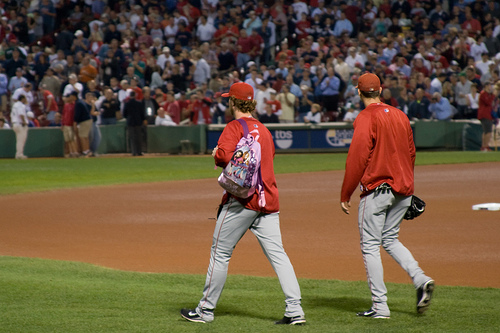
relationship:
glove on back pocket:
[375, 182, 391, 192] [375, 187, 395, 213]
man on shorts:
[69, 87, 100, 159] [75, 118, 97, 139]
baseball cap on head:
[355, 73, 380, 91] [353, 71, 383, 100]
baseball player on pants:
[179, 82, 308, 325] [207, 217, 296, 314]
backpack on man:
[218, 127, 275, 214] [328, 64, 458, 323]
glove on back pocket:
[371, 183, 389, 195] [375, 187, 395, 211]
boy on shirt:
[300, 102, 322, 124] [303, 110, 321, 122]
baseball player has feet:
[340, 72, 434, 320] [364, 289, 441, 318]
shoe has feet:
[355, 305, 391, 322] [364, 289, 441, 318]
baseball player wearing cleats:
[340, 72, 434, 320] [414, 279, 438, 319]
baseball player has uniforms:
[179, 82, 308, 325] [174, 67, 436, 327]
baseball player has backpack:
[179, 82, 308, 325] [218, 119, 262, 196]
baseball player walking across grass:
[340, 72, 434, 320] [9, 257, 481, 331]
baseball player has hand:
[340, 72, 434, 320] [338, 196, 363, 216]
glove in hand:
[404, 179, 423, 216] [338, 196, 363, 216]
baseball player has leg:
[179, 82, 308, 325] [255, 231, 303, 324]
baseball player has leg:
[179, 82, 308, 325] [195, 200, 257, 312]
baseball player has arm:
[340, 72, 434, 320] [341, 119, 386, 209]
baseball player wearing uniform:
[340, 72, 434, 320] [337, 100, 430, 308]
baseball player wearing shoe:
[340, 72, 434, 320] [349, 304, 395, 321]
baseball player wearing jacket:
[340, 72, 434, 320] [339, 101, 419, 201]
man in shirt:
[316, 64, 344, 112] [317, 74, 341, 94]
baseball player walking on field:
[336, 71, 436, 323] [4, 152, 499, 329]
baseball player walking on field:
[178, 80, 308, 325] [4, 152, 499, 329]